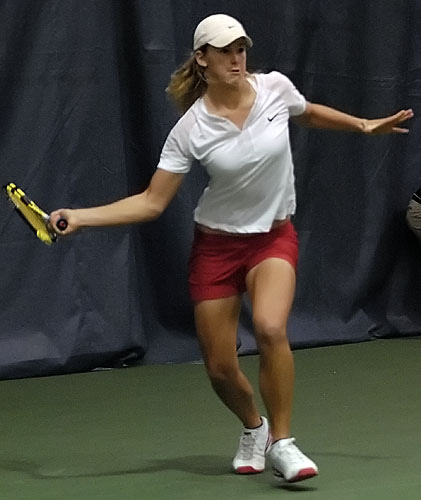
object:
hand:
[47, 208, 78, 236]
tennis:
[4, 15, 416, 487]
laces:
[240, 433, 257, 460]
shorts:
[188, 216, 299, 304]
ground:
[0, 338, 421, 499]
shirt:
[156, 68, 307, 234]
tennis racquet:
[2, 179, 67, 244]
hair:
[164, 51, 208, 118]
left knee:
[252, 309, 285, 340]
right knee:
[205, 355, 235, 391]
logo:
[268, 114, 277, 121]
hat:
[193, 13, 253, 51]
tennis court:
[0, 0, 420, 500]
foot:
[231, 415, 273, 475]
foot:
[264, 433, 318, 484]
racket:
[5, 179, 69, 249]